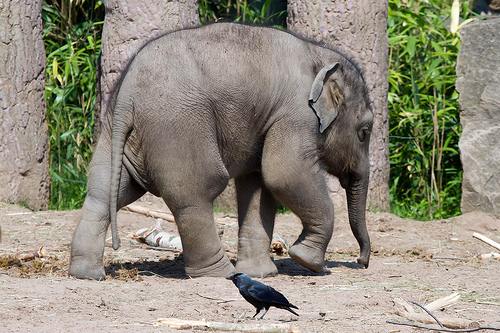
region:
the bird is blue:
[224, 270, 296, 317]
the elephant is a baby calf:
[77, 58, 377, 268]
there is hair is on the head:
[333, 51, 366, 105]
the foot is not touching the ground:
[262, 141, 338, 276]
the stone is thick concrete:
[455, 36, 497, 212]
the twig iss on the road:
[399, 296, 494, 329]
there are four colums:
[1, 18, 498, 215]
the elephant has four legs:
[84, 28, 376, 281]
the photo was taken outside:
[2, 17, 498, 322]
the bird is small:
[220, 270, 300, 320]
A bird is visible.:
[193, 253, 280, 330]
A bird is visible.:
[221, 262, 268, 327]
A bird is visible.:
[222, 272, 253, 313]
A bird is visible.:
[196, 247, 243, 317]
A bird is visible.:
[226, 230, 284, 328]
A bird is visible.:
[209, 244, 266, 314]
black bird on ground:
[226, 273, 301, 319]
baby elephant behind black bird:
[65, 22, 370, 277]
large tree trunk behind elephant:
[100, 0, 200, 215]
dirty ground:
[0, 205, 495, 327]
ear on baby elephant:
[310, 61, 345, 133]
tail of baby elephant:
[105, 67, 130, 247]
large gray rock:
[455, 12, 495, 217]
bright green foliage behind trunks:
[42, 0, 467, 210]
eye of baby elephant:
[350, 120, 370, 145]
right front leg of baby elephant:
[260, 118, 337, 268]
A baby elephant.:
[40, 31, 405, 279]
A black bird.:
[202, 255, 312, 321]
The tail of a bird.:
[281, 295, 302, 320]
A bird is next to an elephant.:
[49, 13, 394, 330]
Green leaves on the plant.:
[392, 6, 452, 207]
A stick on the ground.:
[368, 287, 494, 328]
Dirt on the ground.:
[10, 280, 141, 321]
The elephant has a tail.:
[86, 85, 147, 261]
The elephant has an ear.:
[306, 53, 349, 133]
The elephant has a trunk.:
[337, 154, 384, 274]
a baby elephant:
[88, 21, 419, 270]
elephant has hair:
[265, 11, 380, 108]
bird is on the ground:
[214, 262, 309, 331]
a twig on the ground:
[397, 300, 499, 324]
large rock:
[453, 22, 493, 236]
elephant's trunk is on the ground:
[312, 75, 419, 288]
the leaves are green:
[378, 21, 476, 208]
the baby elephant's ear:
[305, 52, 362, 151]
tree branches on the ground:
[140, 211, 318, 268]